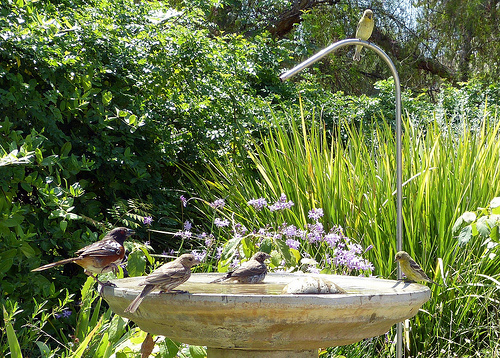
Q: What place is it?
A: It is a garden.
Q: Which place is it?
A: It is a garden.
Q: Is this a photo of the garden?
A: Yes, it is showing the garden.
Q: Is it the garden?
A: Yes, it is the garden.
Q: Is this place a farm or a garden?
A: It is a garden.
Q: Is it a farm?
A: No, it is a garden.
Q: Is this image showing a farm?
A: No, the picture is showing a garden.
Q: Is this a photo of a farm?
A: No, the picture is showing a garden.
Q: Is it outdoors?
A: Yes, it is outdoors.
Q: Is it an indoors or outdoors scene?
A: It is outdoors.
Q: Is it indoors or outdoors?
A: It is outdoors.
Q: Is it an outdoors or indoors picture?
A: It is outdoors.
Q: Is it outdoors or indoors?
A: It is outdoors.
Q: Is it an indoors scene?
A: No, it is outdoors.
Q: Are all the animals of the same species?
A: Yes, all the animals are birds.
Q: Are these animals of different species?
A: No, all the animals are birds.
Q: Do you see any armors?
A: No, there are no armors.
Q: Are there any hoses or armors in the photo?
A: No, there are no armors or hoses.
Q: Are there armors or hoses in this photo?
A: No, there are no armors or hoses.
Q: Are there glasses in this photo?
A: No, there are no glasses.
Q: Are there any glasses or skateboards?
A: No, there are no glasses or skateboards.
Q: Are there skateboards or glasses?
A: No, there are no glasses or skateboards.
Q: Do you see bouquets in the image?
A: No, there are no bouquets.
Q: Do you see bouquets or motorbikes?
A: No, there are no bouquets or motorbikes.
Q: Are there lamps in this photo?
A: No, there are no lamps.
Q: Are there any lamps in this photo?
A: No, there are no lamps.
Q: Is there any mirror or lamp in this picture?
A: No, there are no lamps or mirrors.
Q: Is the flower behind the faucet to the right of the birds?
A: Yes, the flower is behind the tap.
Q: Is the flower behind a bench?
A: No, the flower is behind the tap.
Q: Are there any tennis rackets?
A: No, there are no tennis rackets.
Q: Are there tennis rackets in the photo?
A: No, there are no tennis rackets.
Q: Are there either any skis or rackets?
A: No, there are no rackets or skis.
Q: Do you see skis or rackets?
A: No, there are no rackets or skis.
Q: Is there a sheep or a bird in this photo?
A: Yes, there is a bird.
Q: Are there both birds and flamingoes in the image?
A: No, there is a bird but no flamingoes.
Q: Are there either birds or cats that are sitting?
A: Yes, the bird is sitting.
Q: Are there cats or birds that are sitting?
A: Yes, the bird is sitting.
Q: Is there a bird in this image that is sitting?
A: Yes, there is a bird that is sitting.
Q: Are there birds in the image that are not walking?
A: Yes, there is a bird that is sitting.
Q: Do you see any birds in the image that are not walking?
A: Yes, there is a bird that is sitting .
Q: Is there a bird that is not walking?
A: Yes, there is a bird that is sitting.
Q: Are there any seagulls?
A: No, there are no seagulls.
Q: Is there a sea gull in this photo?
A: No, there are no seagulls.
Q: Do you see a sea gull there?
A: No, there are no seagulls.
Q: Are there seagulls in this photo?
A: No, there are no seagulls.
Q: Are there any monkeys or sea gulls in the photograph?
A: No, there are no sea gulls or monkeys.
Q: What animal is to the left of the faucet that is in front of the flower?
A: The animal is a bird.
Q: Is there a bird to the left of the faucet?
A: Yes, there is a bird to the left of the faucet.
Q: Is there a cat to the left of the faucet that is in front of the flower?
A: No, there is a bird to the left of the faucet.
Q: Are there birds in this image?
A: Yes, there is a bird.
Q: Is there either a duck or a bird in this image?
A: Yes, there is a bird.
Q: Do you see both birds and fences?
A: No, there is a bird but no fences.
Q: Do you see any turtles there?
A: No, there are no turtles.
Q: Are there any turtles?
A: No, there are no turtles.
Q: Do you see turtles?
A: No, there are no turtles.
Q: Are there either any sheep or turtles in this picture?
A: No, there are no turtles or sheep.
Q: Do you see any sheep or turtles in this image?
A: No, there are no turtles or sheep.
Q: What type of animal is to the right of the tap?
A: The animal is a bird.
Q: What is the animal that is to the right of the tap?
A: The animal is a bird.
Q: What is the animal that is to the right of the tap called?
A: The animal is a bird.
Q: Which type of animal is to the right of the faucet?
A: The animal is a bird.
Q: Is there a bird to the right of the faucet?
A: Yes, there is a bird to the right of the faucet.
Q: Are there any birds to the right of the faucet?
A: Yes, there is a bird to the right of the faucet.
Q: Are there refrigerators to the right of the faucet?
A: No, there is a bird to the right of the faucet.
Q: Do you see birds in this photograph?
A: Yes, there is a bird.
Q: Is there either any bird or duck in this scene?
A: Yes, there is a bird.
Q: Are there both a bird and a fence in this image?
A: No, there is a bird but no fences.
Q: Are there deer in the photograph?
A: No, there are no deer.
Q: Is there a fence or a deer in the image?
A: No, there are no deer or fences.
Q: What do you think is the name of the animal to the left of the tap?
A: The animal is a bird.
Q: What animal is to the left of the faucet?
A: The animal is a bird.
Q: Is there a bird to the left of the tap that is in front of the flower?
A: Yes, there is a bird to the left of the faucet.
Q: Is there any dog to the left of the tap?
A: No, there is a bird to the left of the tap.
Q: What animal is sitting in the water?
A: The bird is sitting in the water.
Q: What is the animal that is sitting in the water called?
A: The animal is a bird.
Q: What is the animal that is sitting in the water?
A: The animal is a bird.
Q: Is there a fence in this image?
A: No, there are no fences.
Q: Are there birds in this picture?
A: Yes, there are birds.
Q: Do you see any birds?
A: Yes, there are birds.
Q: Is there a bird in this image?
A: Yes, there are birds.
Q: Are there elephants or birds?
A: Yes, there are birds.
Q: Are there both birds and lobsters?
A: No, there are birds but no lobsters.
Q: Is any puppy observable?
A: No, there are no puppys.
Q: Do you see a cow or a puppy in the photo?
A: No, there are no puppys or cows.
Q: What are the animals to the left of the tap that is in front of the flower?
A: The animals are birds.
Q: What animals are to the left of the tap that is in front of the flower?
A: The animals are birds.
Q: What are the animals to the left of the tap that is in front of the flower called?
A: The animals are birds.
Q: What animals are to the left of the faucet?
A: The animals are birds.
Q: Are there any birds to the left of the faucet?
A: Yes, there are birds to the left of the faucet.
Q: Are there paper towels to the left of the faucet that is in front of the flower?
A: No, there are birds to the left of the tap.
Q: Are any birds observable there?
A: Yes, there is a bird.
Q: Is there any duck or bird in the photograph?
A: Yes, there is a bird.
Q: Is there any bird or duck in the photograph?
A: Yes, there is a bird.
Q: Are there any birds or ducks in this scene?
A: Yes, there is a bird.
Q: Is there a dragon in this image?
A: No, there are no dragons.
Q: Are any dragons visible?
A: No, there are no dragons.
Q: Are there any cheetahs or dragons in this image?
A: No, there are no dragons or cheetahs.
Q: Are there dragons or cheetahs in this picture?
A: No, there are no dragons or cheetahs.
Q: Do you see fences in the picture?
A: No, there are no fences.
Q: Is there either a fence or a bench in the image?
A: No, there are no fences or benches.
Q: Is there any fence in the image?
A: No, there are no fences.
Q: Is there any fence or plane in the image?
A: No, there are no fences or airplanes.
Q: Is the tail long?
A: Yes, the tail is long.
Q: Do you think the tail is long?
A: Yes, the tail is long.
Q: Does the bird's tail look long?
A: Yes, the tail is long.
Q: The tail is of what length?
A: The tail is long.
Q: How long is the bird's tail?
A: The tail is long.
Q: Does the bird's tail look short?
A: No, the tail is long.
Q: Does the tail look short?
A: No, the tail is long.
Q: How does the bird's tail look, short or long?
A: The tail is long.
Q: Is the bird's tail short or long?
A: The tail is long.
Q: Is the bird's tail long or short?
A: The tail is long.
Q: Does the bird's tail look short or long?
A: The tail is long.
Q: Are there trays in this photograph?
A: No, there are no trays.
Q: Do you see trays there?
A: No, there are no trays.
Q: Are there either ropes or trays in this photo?
A: No, there are no trays or ropes.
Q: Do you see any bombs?
A: No, there are no bombs.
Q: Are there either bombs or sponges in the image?
A: No, there are no bombs or sponges.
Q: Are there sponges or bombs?
A: No, there are no bombs or sponges.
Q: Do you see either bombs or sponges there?
A: No, there are no bombs or sponges.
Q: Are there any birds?
A: Yes, there is a bird.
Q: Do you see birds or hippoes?
A: Yes, there is a bird.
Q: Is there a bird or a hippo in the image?
A: Yes, there is a bird.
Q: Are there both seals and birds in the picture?
A: No, there is a bird but no seals.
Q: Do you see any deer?
A: No, there are no deer.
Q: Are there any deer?
A: No, there are no deer.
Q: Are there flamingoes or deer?
A: No, there are no deer or flamingoes.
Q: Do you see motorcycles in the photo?
A: No, there are no motorcycles.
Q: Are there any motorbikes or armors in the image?
A: No, there are no motorbikes or armors.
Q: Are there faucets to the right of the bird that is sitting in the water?
A: Yes, there is a faucet to the right of the bird.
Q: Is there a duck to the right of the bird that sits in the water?
A: No, there is a faucet to the right of the bird.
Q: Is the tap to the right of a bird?
A: Yes, the tap is to the right of a bird.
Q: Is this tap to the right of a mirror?
A: No, the tap is to the right of a bird.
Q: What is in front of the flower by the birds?
A: The faucet is in front of the flower.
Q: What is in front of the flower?
A: The faucet is in front of the flower.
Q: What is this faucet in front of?
A: The faucet is in front of the flower.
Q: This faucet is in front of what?
A: The faucet is in front of the flower.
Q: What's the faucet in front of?
A: The faucet is in front of the flower.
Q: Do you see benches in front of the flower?
A: No, there is a faucet in front of the flower.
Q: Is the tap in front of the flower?
A: Yes, the tap is in front of the flower.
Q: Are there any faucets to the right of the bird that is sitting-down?
A: Yes, there is a faucet to the right of the bird.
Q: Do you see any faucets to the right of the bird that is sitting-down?
A: Yes, there is a faucet to the right of the bird.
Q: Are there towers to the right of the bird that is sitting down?
A: No, there is a faucet to the right of the bird.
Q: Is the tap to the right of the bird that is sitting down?
A: Yes, the tap is to the right of the bird.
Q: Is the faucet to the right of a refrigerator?
A: No, the faucet is to the right of the bird.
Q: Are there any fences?
A: No, there are no fences.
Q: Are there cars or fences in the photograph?
A: No, there are no fences or cars.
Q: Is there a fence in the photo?
A: No, there are no fences.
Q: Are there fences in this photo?
A: No, there are no fences.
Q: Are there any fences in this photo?
A: No, there are no fences.